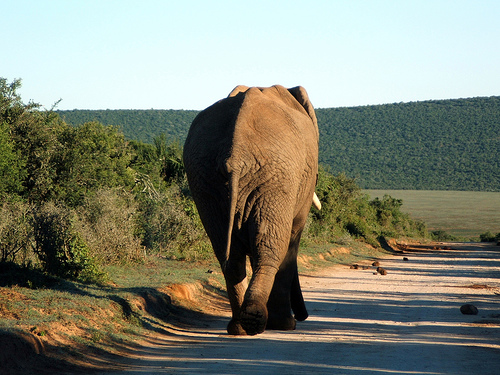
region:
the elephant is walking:
[162, 56, 307, 373]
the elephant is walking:
[157, 53, 327, 366]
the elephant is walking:
[170, 65, 332, 373]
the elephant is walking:
[157, 55, 319, 370]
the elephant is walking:
[157, 46, 334, 346]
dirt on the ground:
[326, 234, 409, 285]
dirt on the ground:
[335, 241, 393, 281]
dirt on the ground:
[329, 222, 412, 297]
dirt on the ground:
[348, 226, 401, 299]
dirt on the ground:
[337, 235, 431, 305]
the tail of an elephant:
[220, 165, 240, 277]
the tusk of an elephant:
[311, 185, 326, 210]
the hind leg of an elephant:
[239, 195, 295, 335]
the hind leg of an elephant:
[198, 220, 246, 338]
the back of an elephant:
[226, 82, 266, 157]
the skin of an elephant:
[267, 112, 312, 171]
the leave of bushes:
[325, 188, 365, 219]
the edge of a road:
[23, 272, 201, 353]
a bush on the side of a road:
[23, 200, 98, 288]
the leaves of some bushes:
[26, 123, 83, 180]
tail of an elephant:
[218, 162, 248, 261]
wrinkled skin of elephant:
[254, 170, 293, 226]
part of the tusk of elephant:
[308, 188, 323, 209]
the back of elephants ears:
[293, 83, 318, 124]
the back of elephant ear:
[222, 83, 247, 100]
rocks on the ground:
[351, 256, 388, 276]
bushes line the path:
[1, 110, 183, 273]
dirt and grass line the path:
[3, 277, 192, 337]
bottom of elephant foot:
[238, 294, 268, 334]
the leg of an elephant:
[243, 218, 285, 305]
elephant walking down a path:
[180, 83, 320, 338]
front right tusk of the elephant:
[311, 194, 322, 213]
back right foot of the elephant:
[236, 212, 288, 337]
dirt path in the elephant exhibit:
[70, 244, 497, 374]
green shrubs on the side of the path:
[2, 96, 415, 246]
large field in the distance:
[358, 190, 496, 241]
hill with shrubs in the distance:
[49, 98, 494, 196]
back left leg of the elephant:
[211, 212, 256, 344]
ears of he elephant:
[215, 84, 317, 126]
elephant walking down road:
[172, 68, 332, 347]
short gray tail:
[212, 148, 244, 266]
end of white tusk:
[306, 178, 331, 220]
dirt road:
[373, 280, 432, 362]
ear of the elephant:
[290, 83, 332, 152]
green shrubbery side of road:
[25, 107, 156, 275]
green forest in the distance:
[92, 83, 187, 139]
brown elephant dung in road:
[346, 245, 386, 295]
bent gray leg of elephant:
[231, 255, 282, 331]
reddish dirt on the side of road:
[147, 270, 208, 310]